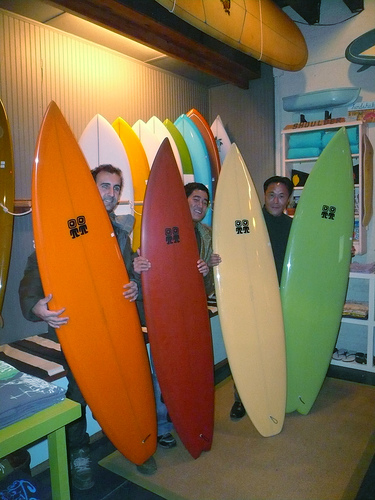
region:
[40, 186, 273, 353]
Surfboards in the photo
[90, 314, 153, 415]
An orange surfboard in the room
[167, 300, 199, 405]
A red surfboard in the room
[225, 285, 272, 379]
A brown surfboard in the room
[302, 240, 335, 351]
A green surfboard in the room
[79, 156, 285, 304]
Three people holding surfboards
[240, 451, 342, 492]
A mat in the room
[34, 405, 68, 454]
A table in the photo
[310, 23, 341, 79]
A wall in the room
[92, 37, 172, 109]
Light on the wall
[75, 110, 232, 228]
row of surfboards against wall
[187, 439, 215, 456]
notched tail of surfboard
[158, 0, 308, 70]
surfboard hanging from ceiling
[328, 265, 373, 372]
blue cabinet sitting on floor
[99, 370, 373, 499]
light brown area rug with light green trip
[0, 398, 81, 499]
green table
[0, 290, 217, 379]
striped bench cushion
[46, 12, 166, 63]
interior recessed light fixture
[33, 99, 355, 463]
orange red white and green surfboards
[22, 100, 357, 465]
three men holding four surfboards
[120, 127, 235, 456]
man carrying a surfboard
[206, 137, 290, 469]
man carrying a surfboard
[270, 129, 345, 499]
man carrying a surfboard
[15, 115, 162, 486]
man carrying a surfboard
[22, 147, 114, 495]
the surfboard is orange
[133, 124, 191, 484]
the surfboard is red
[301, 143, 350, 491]
the surfboard is green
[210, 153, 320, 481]
the surfboard is beige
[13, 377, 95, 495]
the table is green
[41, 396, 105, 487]
the table is green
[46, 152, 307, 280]
three men standing with surfboards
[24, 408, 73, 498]
green table with tee shirts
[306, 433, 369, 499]
beige and green rug on the floor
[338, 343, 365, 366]
shoes on the bottom shelf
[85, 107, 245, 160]
surfboards against the wall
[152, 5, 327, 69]
surfboard hanging from the ceiling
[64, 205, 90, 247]
two caricatures on the surfboard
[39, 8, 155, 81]
light shining against the wall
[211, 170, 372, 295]
man holding two surfboards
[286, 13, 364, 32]
cord hanging on the wall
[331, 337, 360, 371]
the slippers are white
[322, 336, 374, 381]
the slippers are white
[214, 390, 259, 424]
the shoe is black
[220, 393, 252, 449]
the shoe is black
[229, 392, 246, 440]
the shoe is black